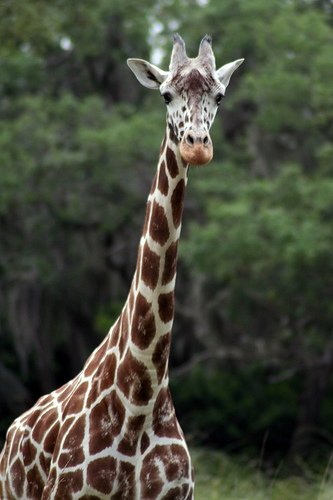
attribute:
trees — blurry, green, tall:
[13, 19, 249, 317]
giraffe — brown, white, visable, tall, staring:
[11, 55, 209, 496]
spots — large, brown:
[54, 420, 191, 489]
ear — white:
[131, 62, 165, 90]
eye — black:
[162, 90, 176, 109]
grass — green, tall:
[196, 454, 317, 492]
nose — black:
[186, 125, 211, 161]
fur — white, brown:
[155, 206, 180, 240]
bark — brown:
[194, 303, 234, 365]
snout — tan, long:
[176, 130, 214, 168]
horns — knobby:
[152, 42, 215, 65]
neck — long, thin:
[129, 156, 170, 339]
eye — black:
[206, 84, 238, 111]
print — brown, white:
[79, 351, 129, 460]